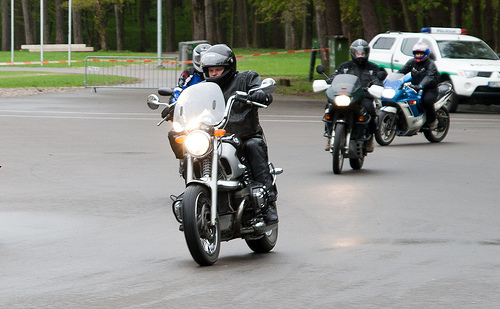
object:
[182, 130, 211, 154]
headlight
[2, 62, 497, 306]
street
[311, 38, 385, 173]
rider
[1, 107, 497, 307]
lane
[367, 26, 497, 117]
car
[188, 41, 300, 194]
rider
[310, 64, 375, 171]
motorcycle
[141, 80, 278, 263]
motorcycle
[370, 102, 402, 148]
wheel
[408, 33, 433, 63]
hemet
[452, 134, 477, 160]
ground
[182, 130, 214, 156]
light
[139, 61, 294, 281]
bike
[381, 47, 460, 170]
bike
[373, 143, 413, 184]
ground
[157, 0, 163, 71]
pole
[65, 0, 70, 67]
pole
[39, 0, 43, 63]
pole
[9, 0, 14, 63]
pole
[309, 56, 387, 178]
machine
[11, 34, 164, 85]
grassy field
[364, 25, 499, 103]
police car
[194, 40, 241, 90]
helmet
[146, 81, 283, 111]
mirrors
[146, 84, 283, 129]
handlebars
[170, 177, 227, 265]
motor bike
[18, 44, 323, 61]
caution tape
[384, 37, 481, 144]
rider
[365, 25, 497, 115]
suv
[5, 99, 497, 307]
parking lot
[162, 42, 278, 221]
man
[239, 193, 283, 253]
wheel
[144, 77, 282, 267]
motorbike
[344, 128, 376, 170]
wheel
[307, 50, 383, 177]
bike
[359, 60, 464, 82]
stripe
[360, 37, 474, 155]
motorcycle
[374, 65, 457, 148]
motor bike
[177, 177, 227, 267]
black tire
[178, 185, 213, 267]
wheel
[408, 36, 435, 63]
red/white helmet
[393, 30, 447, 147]
rider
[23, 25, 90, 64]
bleachers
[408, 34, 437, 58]
helmet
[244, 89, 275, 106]
glove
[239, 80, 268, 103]
left hand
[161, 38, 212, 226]
rider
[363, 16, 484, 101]
vehicle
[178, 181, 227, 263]
wheel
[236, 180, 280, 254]
wheel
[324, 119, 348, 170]
wheel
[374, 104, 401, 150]
wheel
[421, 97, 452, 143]
wheel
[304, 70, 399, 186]
motorbike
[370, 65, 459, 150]
motorbike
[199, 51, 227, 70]
visor